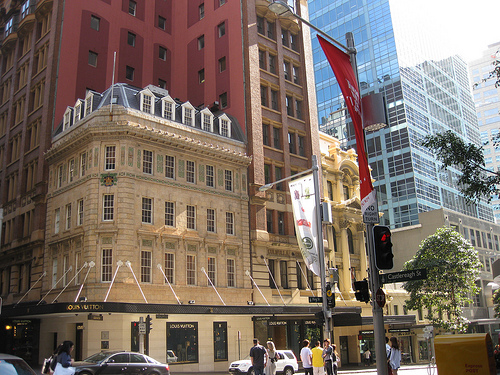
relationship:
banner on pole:
[261, 156, 345, 306] [213, 139, 356, 230]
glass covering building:
[314, 3, 476, 229] [307, 1, 483, 261]